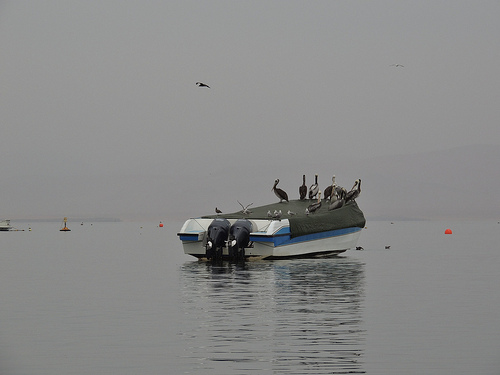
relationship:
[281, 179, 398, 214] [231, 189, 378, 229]
birds on cover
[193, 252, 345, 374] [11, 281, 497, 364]
reflection on surface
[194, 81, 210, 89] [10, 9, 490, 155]
bird on air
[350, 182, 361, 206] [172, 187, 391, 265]
pelican on boat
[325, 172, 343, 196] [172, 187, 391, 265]
pelican on boat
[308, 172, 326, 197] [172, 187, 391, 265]
pelican on boat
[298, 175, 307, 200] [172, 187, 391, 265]
bird on boat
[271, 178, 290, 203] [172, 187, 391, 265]
bird on boat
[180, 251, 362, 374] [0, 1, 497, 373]
reflection on water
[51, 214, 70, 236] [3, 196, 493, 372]
buoy in water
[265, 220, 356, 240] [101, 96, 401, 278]
stripe on boat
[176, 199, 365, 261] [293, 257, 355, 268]
boat floating on water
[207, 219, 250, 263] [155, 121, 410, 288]
motor on boat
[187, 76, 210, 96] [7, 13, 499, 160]
bird flying in sky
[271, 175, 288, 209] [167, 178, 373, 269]
bird sitting on boat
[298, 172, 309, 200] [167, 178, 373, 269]
bird sitting on boat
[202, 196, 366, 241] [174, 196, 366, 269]
tarp covering boat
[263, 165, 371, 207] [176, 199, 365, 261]
pelicans on top boat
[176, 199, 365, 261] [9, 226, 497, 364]
boat in water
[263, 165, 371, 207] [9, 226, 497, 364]
pelicans on top water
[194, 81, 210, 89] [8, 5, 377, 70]
bird flying in sky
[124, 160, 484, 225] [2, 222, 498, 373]
fog-covered hill by water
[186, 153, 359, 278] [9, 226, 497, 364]
boat in water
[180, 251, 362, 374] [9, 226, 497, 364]
reflection in water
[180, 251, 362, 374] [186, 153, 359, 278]
reflection of boat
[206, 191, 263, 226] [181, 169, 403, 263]
seagulls sitting on a motor boat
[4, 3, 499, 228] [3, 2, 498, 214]
clouds cover in sky